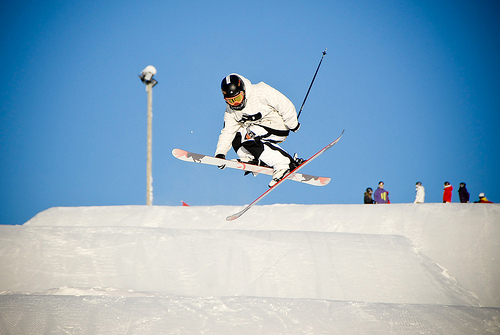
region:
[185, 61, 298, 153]
the jacket is white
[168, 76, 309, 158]
the jacket is white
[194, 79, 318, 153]
the jacket is white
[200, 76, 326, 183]
the jacket is white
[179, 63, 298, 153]
the jacket is white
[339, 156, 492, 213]
the people standing on the snow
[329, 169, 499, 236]
the people standing on the snow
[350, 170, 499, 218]
the people standing on the snow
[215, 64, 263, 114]
black helmet on skier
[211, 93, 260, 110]
orange reflective goggles on person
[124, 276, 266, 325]
tracks on top of white snow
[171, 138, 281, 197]
white bottom of person's ski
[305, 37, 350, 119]
black metal ski pole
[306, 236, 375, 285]
clear patch of flat snow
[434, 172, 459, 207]
person in red snow attire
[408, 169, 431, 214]
person in white snow attire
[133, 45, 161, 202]
tall white pole in background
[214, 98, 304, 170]
white and black outfit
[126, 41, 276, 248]
a person riding skies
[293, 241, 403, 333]
a ground covered in snow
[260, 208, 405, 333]
a ground covered in white snow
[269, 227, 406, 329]
snow covering the ground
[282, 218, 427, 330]
white snow covering the ground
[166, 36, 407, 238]
a skier in the air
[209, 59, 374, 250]
a skier wearing a helmet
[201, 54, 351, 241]
a skier wearing a jacket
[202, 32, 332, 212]
a skier wearing a white jacket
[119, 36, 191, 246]
a pole in the snow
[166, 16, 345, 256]
a man snow skiing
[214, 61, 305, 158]
a man wearing a white and black snow suit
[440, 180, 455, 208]
a person wearing a red coat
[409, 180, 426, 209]
a person wearing a white coat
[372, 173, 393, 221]
a person wearing a purple coat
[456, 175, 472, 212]
a person wearing black clothing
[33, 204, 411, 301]
small hills in the snow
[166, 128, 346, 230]
a pair of snow skis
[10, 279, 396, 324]
tracks in the snow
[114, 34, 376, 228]
Skier in mid-air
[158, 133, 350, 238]
Skis worn by a skier in midair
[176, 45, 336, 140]
Ski pole held by a skier in midair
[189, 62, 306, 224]
Skier wearing a black helmet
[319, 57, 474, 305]
People at the top of a ski hill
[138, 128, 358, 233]
Skis crossed in mid-air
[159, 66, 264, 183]
Skier holding one of his skis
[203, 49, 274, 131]
Skier wearing gold colored goggles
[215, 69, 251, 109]
person wearing a black helmet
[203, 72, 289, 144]
person wearing a white jacket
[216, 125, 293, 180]
person wearing black pants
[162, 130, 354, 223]
person on skis in the air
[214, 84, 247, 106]
person wearing ski goggles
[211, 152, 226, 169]
person wearing black gloves